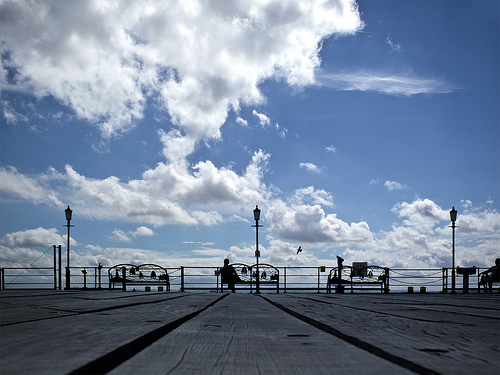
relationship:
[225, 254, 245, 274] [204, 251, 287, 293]
man on bench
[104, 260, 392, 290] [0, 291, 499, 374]
benches on pier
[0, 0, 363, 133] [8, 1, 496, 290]
cloud in sky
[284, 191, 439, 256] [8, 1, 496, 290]
clouds in sky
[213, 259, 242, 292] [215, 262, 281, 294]
man sitting on bench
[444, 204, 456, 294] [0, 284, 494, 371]
pole on platform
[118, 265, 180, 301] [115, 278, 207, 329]
bench on platform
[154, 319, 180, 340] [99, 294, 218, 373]
crack between boards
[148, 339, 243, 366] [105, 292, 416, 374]
grains on plank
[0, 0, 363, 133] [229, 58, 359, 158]
cloud in sky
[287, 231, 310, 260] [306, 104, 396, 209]
bird in sky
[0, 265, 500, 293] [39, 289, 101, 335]
fence on platform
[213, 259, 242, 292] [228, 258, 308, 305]
man on bench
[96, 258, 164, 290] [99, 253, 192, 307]
design on bench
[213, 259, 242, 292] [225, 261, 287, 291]
man on bench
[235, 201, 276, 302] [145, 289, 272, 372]
pole on pier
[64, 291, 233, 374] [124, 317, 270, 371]
crack between planks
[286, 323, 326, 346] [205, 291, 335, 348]
hole in plank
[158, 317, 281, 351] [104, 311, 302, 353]
plank on pier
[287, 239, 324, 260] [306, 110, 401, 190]
birds in sky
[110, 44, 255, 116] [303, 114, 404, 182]
cloud in sky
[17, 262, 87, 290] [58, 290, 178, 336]
fence at pier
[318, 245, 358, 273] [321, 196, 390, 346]
binoculars on pole